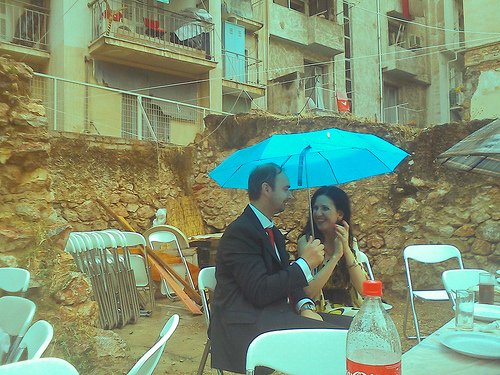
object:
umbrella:
[208, 128, 410, 254]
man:
[206, 161, 354, 373]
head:
[246, 161, 293, 214]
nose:
[286, 190, 293, 200]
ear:
[260, 182, 270, 196]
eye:
[282, 185, 289, 191]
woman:
[295, 182, 367, 320]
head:
[310, 184, 349, 233]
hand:
[300, 233, 324, 269]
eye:
[321, 205, 328, 211]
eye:
[312, 204, 320, 211]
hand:
[333, 217, 351, 249]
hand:
[333, 234, 345, 259]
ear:
[336, 208, 343, 221]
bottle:
[343, 279, 403, 374]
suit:
[205, 201, 358, 374]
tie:
[265, 224, 274, 248]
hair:
[247, 161, 282, 201]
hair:
[300, 184, 352, 273]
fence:
[25, 70, 236, 146]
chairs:
[142, 228, 197, 303]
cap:
[359, 279, 381, 297]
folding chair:
[400, 243, 466, 344]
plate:
[436, 329, 500, 361]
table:
[397, 303, 499, 373]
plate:
[450, 301, 498, 320]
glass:
[453, 288, 478, 332]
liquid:
[477, 282, 494, 306]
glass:
[477, 269, 497, 304]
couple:
[205, 161, 375, 373]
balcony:
[87, 0, 217, 78]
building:
[0, 0, 499, 142]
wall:
[1, 57, 499, 338]